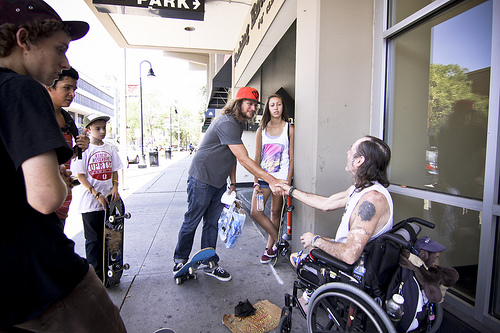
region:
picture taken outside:
[10, 16, 475, 329]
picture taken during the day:
[12, 19, 472, 316]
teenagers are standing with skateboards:
[13, 13, 464, 313]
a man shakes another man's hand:
[207, 64, 403, 258]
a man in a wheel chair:
[232, 121, 452, 331]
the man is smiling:
[232, 84, 264, 118]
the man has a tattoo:
[355, 202, 385, 220]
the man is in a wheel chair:
[297, 121, 451, 325]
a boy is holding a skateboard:
[81, 162, 146, 284]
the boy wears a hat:
[235, 75, 270, 106]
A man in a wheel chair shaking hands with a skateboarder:
[167, 83, 465, 330]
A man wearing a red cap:
[220, 83, 265, 126]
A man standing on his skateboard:
[168, 81, 289, 288]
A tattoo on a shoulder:
[351, 191, 384, 231]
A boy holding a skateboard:
[74, 109, 136, 291]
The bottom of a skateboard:
[100, 194, 134, 289]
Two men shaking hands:
[167, 80, 460, 328]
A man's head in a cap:
[5, 5, 91, 90]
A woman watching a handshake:
[250, 89, 297, 269]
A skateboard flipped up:
[167, 242, 220, 292]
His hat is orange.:
[235, 88, 260, 109]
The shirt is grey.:
[189, 117, 244, 187]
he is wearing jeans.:
[167, 170, 227, 263]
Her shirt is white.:
[246, 126, 293, 183]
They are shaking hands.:
[163, 84, 475, 330]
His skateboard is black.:
[97, 186, 137, 293]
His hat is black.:
[75, 105, 111, 132]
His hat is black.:
[3, 1, 90, 48]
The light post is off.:
[133, 46, 154, 166]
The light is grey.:
[135, 51, 161, 160]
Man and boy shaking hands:
[172, 85, 439, 332]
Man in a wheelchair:
[276, 130, 446, 332]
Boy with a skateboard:
[172, 85, 267, 291]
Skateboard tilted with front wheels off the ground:
[172, 245, 217, 287]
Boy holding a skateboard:
[76, 108, 133, 288]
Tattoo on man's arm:
[356, 197, 375, 222]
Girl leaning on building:
[247, 88, 294, 265]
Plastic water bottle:
[253, 184, 265, 214]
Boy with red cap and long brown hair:
[223, 81, 262, 136]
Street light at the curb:
[135, 59, 156, 173]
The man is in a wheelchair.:
[276, 133, 458, 331]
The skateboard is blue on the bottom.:
[173, 247, 218, 286]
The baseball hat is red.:
[234, 85, 266, 104]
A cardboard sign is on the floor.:
[221, 297, 288, 332]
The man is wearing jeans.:
[172, 173, 227, 264]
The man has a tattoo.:
[356, 200, 377, 223]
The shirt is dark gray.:
[187, 107, 243, 189]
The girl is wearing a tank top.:
[260, 120, 290, 181]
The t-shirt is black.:
[0, 65, 90, 326]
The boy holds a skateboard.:
[76, 111, 131, 288]